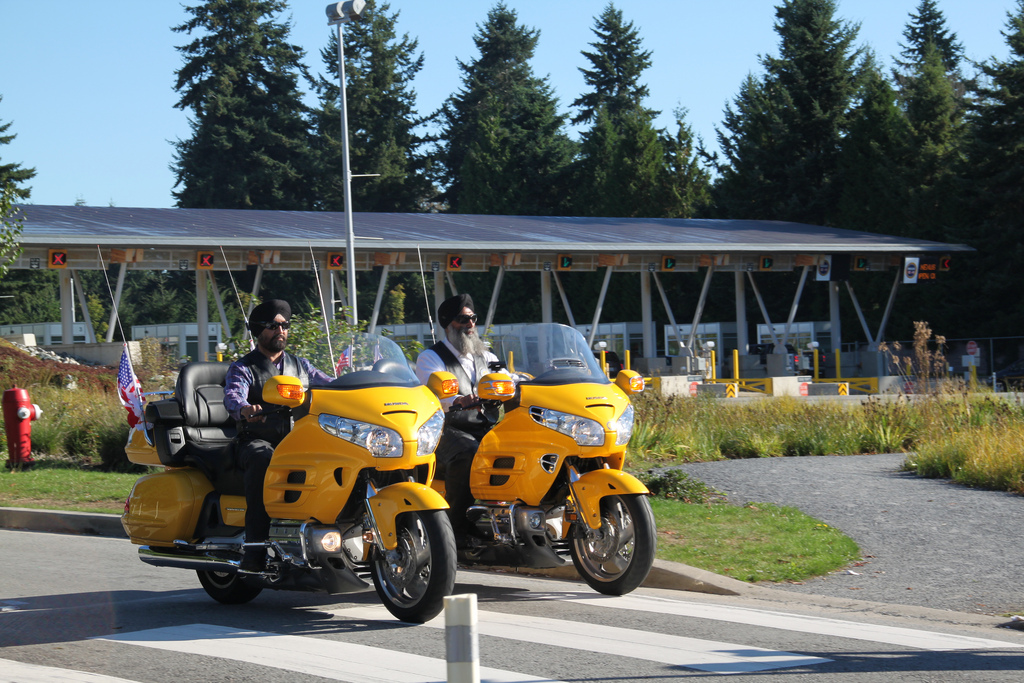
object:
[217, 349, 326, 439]
shirt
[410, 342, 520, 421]
shirt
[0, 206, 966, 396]
shelter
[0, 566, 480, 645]
shadows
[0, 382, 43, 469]
fire hydrant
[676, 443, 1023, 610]
path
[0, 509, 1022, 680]
road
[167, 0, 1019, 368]
trees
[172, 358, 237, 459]
seat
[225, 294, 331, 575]
man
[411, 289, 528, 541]
man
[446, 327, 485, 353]
beard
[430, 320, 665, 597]
motorcycle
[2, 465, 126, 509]
grass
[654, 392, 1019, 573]
grass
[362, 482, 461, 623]
wheel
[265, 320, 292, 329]
sunglasses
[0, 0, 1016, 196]
sky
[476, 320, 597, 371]
windshield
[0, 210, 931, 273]
covering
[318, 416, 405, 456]
headlight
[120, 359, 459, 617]
bike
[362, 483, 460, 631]
tire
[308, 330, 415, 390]
shield